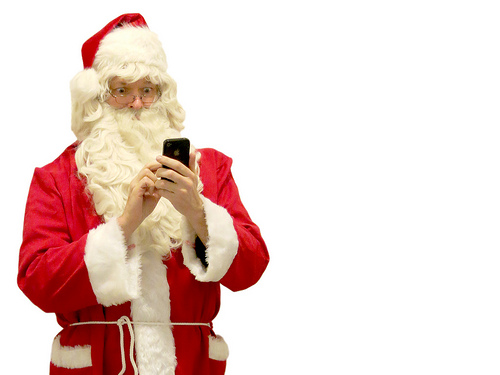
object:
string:
[112, 308, 139, 374]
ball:
[68, 68, 101, 100]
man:
[18, 13, 274, 373]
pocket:
[51, 332, 93, 374]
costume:
[16, 12, 269, 373]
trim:
[201, 337, 228, 362]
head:
[65, 12, 190, 131]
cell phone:
[162, 136, 193, 196]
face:
[69, 62, 189, 146]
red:
[37, 203, 62, 223]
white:
[107, 37, 148, 64]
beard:
[72, 99, 188, 260]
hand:
[150, 152, 201, 217]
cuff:
[85, 216, 143, 309]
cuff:
[181, 195, 238, 282]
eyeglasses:
[103, 84, 165, 104]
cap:
[78, 11, 174, 76]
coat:
[14, 138, 273, 375]